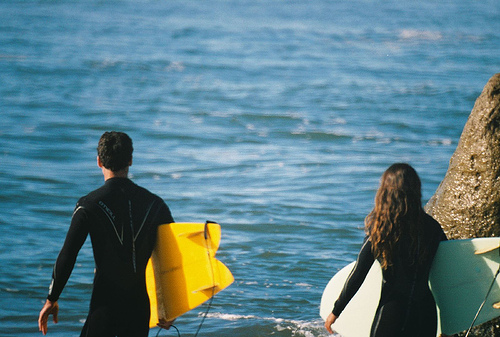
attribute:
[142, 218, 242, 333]
surfboard — orange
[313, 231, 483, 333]
surfboard — white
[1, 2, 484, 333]
ocean water — dark blue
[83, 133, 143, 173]
hair — black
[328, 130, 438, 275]
hair — brown, long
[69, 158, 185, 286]
suit — black, white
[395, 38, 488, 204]
boulder — large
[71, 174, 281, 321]
board — yellow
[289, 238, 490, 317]
board — white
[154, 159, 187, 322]
board — yellow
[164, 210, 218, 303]
board — yellow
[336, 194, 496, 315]
board — white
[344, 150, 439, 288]
hair — brown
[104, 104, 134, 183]
hair — black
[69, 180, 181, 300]
suit — black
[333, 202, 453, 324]
suit — black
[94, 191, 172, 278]
design — grey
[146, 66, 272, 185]
ocean — blue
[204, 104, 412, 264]
waves — small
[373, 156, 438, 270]
hair — long, curly, brown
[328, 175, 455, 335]
wet suit — black, shiny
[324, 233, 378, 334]
arm — long, black, shiny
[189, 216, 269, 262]
strings — black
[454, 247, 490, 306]
surf board — white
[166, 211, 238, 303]
surf board — yellow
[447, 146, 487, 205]
rock — tall, brown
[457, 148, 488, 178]
holes — deep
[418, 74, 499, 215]
rock — brown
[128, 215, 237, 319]
surf board — yellow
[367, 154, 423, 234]
hair — long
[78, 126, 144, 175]
hair — short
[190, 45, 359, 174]
water — blue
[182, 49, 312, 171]
water — blue